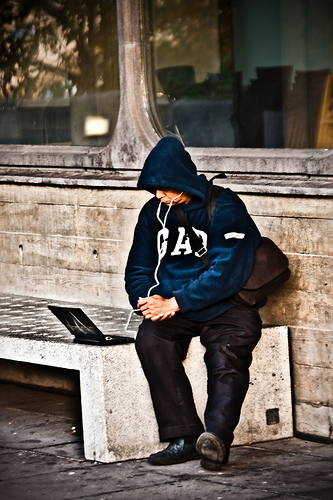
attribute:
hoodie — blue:
[123, 136, 266, 318]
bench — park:
[4, 285, 298, 484]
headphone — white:
[139, 199, 171, 300]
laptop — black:
[43, 299, 135, 348]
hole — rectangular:
[265, 410, 278, 424]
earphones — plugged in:
[99, 182, 188, 330]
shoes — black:
[149, 423, 237, 482]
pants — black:
[134, 284, 260, 373]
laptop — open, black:
[39, 290, 124, 354]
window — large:
[0, 0, 120, 149]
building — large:
[0, 1, 331, 444]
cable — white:
[124, 206, 177, 329]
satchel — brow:
[203, 200, 305, 302]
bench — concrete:
[3, 286, 310, 461]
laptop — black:
[43, 295, 135, 356]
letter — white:
[154, 225, 173, 260]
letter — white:
[170, 222, 194, 257]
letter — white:
[191, 223, 209, 256]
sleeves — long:
[121, 199, 249, 307]